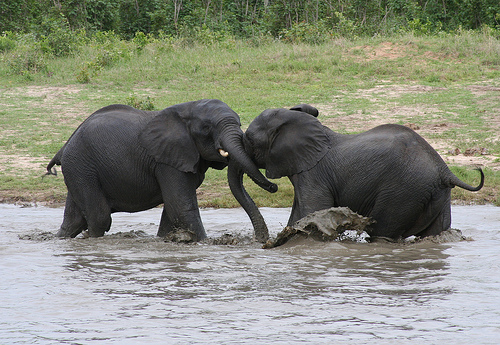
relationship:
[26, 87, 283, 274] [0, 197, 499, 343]
elephant playing in water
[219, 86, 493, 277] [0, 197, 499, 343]
elephant playing in water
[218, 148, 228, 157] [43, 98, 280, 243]
elephant's tusk on elephant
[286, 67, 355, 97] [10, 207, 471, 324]
grass near water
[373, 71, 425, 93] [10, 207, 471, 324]
dirt near water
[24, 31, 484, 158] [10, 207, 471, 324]
land near water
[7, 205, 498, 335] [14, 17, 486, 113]
river meets land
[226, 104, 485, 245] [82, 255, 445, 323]
elephant playing in water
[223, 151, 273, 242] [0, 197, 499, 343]
trunk touching water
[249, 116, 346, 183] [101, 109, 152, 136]
ear touching back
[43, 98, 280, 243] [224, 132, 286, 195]
elephant has trunk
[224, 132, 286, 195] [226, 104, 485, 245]
trunk under elephant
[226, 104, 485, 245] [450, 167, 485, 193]
elephant has tail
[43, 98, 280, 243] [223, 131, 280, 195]
elephant has trunk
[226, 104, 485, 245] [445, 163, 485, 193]
elephant has tail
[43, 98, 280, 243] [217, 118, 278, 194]
elephant has trunk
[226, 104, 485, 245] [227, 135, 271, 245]
elephant has trunk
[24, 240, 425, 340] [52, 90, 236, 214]
water next to elephant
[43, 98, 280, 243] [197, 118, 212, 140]
elephant has eye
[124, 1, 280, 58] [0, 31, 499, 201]
trees behind grass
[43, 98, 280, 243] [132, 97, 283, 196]
elephant has head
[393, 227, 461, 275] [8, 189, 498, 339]
water in lake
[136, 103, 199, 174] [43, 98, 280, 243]
ear on elephant